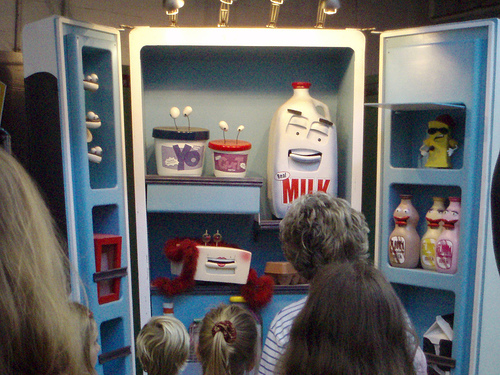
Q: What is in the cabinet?
A: Milk cartoon.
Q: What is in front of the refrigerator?
A: Two children.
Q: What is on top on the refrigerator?
A: Lights.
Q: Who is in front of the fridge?
A: Group of people.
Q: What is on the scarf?
A: A toaster.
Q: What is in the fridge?
A: A milk carton.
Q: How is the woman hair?
A: Gray and black.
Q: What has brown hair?
A: The girl.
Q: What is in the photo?
A: Fake refrigerator.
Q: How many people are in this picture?
A: Six.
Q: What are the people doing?
A: Looking at the refrigerator.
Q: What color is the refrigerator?
A: Blue.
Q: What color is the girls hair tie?
A: Brown.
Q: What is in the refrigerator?
A: Cartoon food.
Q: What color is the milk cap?
A: Red.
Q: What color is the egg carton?
A: Brown.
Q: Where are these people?
A: Outside refrigerator.